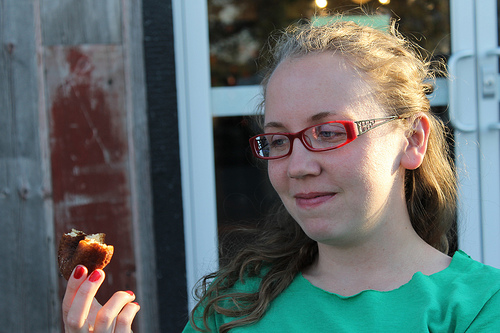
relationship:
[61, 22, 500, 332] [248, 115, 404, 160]
girl wearing glasses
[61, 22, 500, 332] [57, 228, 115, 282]
girl looking at donut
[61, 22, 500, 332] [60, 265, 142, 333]
girl has hand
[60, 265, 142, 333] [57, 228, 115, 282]
hand holding donut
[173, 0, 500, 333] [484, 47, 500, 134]
door has handle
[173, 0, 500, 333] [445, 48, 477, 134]
door has handle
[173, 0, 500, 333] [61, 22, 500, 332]
door behind girl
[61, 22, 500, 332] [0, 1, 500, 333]
girl standing in from of building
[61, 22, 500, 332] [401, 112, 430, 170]
girl has ear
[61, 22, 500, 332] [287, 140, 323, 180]
girl has nose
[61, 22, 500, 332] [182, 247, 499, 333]
girl wearing shirt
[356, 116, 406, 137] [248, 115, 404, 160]
side of glasses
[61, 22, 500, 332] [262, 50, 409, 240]
girl has face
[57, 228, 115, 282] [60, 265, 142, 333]
donut in hand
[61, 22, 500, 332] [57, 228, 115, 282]
girl holding donut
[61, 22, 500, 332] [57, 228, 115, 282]
girl smiling at donut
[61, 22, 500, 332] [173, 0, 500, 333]
girl standing in front of door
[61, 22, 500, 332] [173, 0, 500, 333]
girl standing near door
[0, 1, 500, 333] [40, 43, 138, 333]
building has paint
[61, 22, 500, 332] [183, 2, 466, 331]
girl has hair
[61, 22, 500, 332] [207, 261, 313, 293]
girl has shoulder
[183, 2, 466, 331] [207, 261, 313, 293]
hair laying on shoulder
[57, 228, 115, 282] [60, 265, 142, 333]
donut held in hand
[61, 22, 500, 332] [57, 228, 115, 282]
girl holds donut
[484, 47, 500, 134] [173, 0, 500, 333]
handle of door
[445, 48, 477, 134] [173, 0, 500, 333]
handle of door